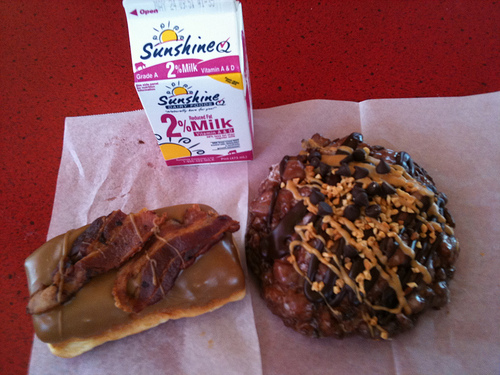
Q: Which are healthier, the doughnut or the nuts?
A: The nuts are healthier than the doughnut.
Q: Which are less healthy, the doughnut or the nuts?
A: The doughnut are less healthy than the nuts.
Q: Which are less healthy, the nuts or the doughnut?
A: The doughnut are less healthy than the nuts.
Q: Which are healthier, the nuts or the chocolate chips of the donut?
A: The nuts are healthier than the chocolate chips.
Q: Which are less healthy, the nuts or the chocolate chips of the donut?
A: The chocolate chips are less healthy than the nuts.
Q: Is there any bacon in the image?
A: Yes, there is bacon.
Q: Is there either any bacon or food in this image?
A: Yes, there is bacon.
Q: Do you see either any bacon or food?
A: Yes, there is bacon.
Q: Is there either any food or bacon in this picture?
A: Yes, there is bacon.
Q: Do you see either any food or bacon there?
A: Yes, there is bacon.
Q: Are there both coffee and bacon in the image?
A: No, there is bacon but no coffee.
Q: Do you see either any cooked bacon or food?
A: Yes, there is cooked bacon.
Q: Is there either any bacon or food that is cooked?
A: Yes, the bacon is cooked.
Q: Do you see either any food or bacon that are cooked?
A: Yes, the bacon is cooked.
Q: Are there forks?
A: No, there are no forks.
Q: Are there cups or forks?
A: No, there are no forks or cups.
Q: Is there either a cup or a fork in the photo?
A: No, there are no forks or cups.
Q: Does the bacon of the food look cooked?
A: Yes, the bacon is cooked.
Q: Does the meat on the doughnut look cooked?
A: Yes, the bacon is cooked.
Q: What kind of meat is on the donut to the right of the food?
A: The meat is bacon.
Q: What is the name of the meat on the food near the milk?
A: The meat is bacon.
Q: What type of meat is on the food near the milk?
A: The meat is bacon.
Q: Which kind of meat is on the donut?
A: The meat is bacon.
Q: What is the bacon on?
A: The bacon is on the donut.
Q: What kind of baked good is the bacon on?
A: The bacon is on the doughnut.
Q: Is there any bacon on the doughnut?
A: Yes, there is bacon on the doughnut.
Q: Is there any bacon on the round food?
A: Yes, there is bacon on the doughnut.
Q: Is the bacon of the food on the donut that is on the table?
A: Yes, the bacon is on the donut.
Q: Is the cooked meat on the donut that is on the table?
A: Yes, the bacon is on the donut.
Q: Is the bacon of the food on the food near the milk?
A: Yes, the bacon is on the donut.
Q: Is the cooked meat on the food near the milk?
A: Yes, the bacon is on the donut.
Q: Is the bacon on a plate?
A: No, the bacon is on the donut.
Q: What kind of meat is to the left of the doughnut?
A: The meat is bacon.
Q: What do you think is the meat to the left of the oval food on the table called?
A: The meat is bacon.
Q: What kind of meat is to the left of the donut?
A: The meat is bacon.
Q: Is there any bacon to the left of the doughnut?
A: Yes, there is bacon to the left of the doughnut.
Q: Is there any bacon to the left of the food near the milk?
A: Yes, there is bacon to the left of the doughnut.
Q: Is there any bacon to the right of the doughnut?
A: No, the bacon is to the left of the doughnut.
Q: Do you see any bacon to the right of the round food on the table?
A: No, the bacon is to the left of the doughnut.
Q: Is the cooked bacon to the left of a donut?
A: Yes, the bacon is to the left of a donut.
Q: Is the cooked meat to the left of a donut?
A: Yes, the bacon is to the left of a donut.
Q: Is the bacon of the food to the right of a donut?
A: No, the bacon is to the left of a donut.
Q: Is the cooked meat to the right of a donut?
A: No, the bacon is to the left of a donut.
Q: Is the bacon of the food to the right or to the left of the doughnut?
A: The bacon is to the left of the doughnut.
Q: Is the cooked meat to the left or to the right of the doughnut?
A: The bacon is to the left of the doughnut.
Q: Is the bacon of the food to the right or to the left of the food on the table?
A: The bacon is to the left of the doughnut.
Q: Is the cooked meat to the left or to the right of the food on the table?
A: The bacon is to the left of the doughnut.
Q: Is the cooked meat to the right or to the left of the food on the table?
A: The bacon is to the left of the doughnut.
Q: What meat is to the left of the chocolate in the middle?
A: The meat is bacon.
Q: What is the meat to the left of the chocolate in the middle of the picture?
A: The meat is bacon.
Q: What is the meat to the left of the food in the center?
A: The meat is bacon.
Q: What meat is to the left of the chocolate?
A: The meat is bacon.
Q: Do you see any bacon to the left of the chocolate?
A: Yes, there is bacon to the left of the chocolate.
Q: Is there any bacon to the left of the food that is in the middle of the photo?
A: Yes, there is bacon to the left of the chocolate.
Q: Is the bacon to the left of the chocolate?
A: Yes, the bacon is to the left of the chocolate.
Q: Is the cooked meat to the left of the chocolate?
A: Yes, the bacon is to the left of the chocolate.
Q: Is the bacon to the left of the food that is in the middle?
A: Yes, the bacon is to the left of the chocolate.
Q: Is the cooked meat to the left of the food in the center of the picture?
A: Yes, the bacon is to the left of the chocolate.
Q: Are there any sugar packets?
A: No, there are no sugar packets.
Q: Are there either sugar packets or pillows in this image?
A: No, there are no sugar packets or pillows.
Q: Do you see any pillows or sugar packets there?
A: No, there are no sugar packets or pillows.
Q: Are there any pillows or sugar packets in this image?
A: No, there are no sugar packets or pillows.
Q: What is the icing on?
A: The icing is on the doughnut.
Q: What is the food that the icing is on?
A: The food is a donut.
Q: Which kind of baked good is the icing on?
A: The icing is on the donut.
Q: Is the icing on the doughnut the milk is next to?
A: Yes, the icing is on the donut.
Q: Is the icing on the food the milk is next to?
A: Yes, the icing is on the donut.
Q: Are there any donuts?
A: Yes, there is a donut.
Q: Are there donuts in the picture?
A: Yes, there is a donut.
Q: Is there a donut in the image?
A: Yes, there is a donut.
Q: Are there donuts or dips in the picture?
A: Yes, there is a donut.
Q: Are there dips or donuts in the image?
A: Yes, there is a donut.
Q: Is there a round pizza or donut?
A: Yes, there is a round donut.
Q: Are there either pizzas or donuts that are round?
A: Yes, the donut is round.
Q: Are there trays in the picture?
A: No, there are no trays.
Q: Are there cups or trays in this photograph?
A: No, there are no trays or cups.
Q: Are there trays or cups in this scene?
A: No, there are no trays or cups.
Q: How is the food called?
A: The food is a donut.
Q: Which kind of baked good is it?
A: The food is a donut.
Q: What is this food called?
A: This is a donut.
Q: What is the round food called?
A: The food is a donut.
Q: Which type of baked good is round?
A: The baked good is a donut.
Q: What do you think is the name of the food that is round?
A: The food is a donut.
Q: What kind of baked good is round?
A: The baked good is a donut.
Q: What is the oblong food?
A: The food is a donut.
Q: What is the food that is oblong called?
A: The food is a donut.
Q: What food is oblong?
A: The food is a donut.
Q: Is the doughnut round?
A: Yes, the doughnut is round.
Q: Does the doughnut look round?
A: Yes, the doughnut is round.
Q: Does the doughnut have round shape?
A: Yes, the doughnut is round.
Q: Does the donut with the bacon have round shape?
A: Yes, the donut is round.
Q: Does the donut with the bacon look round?
A: Yes, the donut is round.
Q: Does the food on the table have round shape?
A: Yes, the donut is round.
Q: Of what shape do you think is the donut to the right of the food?
A: The donut is round.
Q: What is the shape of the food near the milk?
A: The donut is round.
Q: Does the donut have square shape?
A: No, the donut is round.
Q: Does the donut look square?
A: No, the donut is round.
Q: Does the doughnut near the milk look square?
A: No, the doughnut is round.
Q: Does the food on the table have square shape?
A: No, the doughnut is round.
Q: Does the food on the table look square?
A: No, the doughnut is round.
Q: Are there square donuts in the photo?
A: No, there is a donut but it is round.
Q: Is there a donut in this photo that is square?
A: No, there is a donut but it is round.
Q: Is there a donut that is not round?
A: No, there is a donut but it is round.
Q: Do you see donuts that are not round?
A: No, there is a donut but it is round.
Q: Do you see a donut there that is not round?
A: No, there is a donut but it is round.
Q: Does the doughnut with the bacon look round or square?
A: The doughnut is round.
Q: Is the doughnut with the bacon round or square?
A: The doughnut is round.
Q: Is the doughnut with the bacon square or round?
A: The doughnut is round.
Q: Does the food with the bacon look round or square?
A: The doughnut is round.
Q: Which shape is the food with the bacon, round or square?
A: The doughnut is round.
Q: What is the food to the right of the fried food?
A: The food is a donut.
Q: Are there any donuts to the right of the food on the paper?
A: Yes, there is a donut to the right of the food.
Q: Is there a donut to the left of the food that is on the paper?
A: No, the donut is to the right of the food.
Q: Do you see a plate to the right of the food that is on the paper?
A: No, there is a donut to the right of the food.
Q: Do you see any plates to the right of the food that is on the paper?
A: No, there is a donut to the right of the food.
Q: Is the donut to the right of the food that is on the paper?
A: Yes, the donut is to the right of the food.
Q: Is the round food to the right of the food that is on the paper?
A: Yes, the donut is to the right of the food.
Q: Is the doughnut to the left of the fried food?
A: No, the doughnut is to the right of the food.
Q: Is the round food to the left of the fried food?
A: No, the doughnut is to the right of the food.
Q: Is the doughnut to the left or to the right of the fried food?
A: The doughnut is to the right of the food.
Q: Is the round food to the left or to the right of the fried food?
A: The doughnut is to the right of the food.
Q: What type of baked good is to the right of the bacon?
A: The food is a donut.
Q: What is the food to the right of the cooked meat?
A: The food is a donut.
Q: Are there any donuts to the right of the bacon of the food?
A: Yes, there is a donut to the right of the bacon.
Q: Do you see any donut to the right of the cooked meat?
A: Yes, there is a donut to the right of the bacon.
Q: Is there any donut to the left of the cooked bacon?
A: No, the donut is to the right of the bacon.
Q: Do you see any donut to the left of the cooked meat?
A: No, the donut is to the right of the bacon.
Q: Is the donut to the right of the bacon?
A: Yes, the donut is to the right of the bacon.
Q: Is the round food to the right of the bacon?
A: Yes, the donut is to the right of the bacon.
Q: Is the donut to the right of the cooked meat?
A: Yes, the donut is to the right of the bacon.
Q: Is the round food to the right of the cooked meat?
A: Yes, the donut is to the right of the bacon.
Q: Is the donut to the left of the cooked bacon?
A: No, the donut is to the right of the bacon.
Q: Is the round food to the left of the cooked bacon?
A: No, the donut is to the right of the bacon.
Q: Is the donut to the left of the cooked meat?
A: No, the donut is to the right of the bacon.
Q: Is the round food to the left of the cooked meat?
A: No, the donut is to the right of the bacon.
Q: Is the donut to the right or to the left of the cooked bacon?
A: The donut is to the right of the bacon.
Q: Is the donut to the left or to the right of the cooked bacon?
A: The donut is to the right of the bacon.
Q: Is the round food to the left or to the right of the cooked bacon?
A: The donut is to the right of the bacon.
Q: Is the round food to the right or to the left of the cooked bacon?
A: The donut is to the right of the bacon.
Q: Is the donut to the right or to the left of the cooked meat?
A: The donut is to the right of the bacon.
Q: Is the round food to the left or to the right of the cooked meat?
A: The donut is to the right of the bacon.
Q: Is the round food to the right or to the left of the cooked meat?
A: The donut is to the right of the bacon.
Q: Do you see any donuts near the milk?
A: Yes, there is a donut near the milk.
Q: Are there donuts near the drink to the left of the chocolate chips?
A: Yes, there is a donut near the milk.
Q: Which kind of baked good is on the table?
A: The food is a donut.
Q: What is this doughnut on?
A: The doughnut is on the table.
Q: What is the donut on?
A: The doughnut is on the table.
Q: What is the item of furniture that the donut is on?
A: The piece of furniture is a table.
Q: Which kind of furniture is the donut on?
A: The donut is on the table.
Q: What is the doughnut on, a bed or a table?
A: The doughnut is on a table.